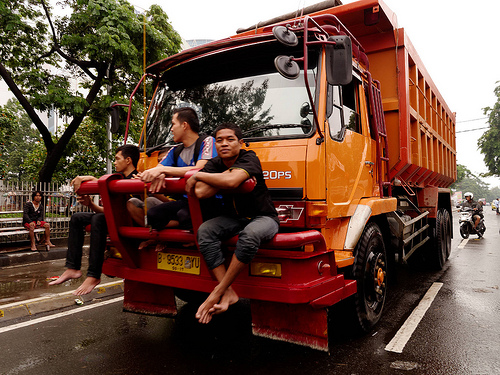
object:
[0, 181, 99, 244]
fence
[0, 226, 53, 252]
bench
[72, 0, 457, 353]
truck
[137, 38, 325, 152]
windshield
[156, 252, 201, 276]
license plate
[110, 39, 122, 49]
leaves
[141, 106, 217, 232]
man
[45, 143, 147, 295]
man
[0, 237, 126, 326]
sidewalk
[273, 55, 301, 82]
mirrors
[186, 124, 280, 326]
boys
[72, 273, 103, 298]
barefoot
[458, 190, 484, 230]
man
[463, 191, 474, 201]
head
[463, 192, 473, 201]
helmet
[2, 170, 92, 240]
fence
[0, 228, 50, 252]
bar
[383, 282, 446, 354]
stripe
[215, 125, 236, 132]
top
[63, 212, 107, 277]
pants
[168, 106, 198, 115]
top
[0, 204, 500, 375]
road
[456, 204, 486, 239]
motorbike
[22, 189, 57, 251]
man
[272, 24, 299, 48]
mirrors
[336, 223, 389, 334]
tire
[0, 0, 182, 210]
tree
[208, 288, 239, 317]
feet